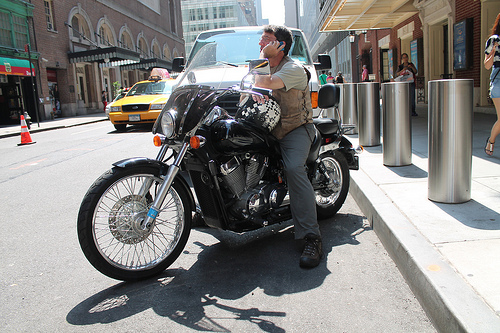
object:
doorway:
[72, 60, 100, 110]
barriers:
[425, 75, 477, 205]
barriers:
[378, 79, 417, 167]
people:
[334, 71, 347, 84]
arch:
[66, 5, 101, 115]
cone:
[16, 112, 38, 147]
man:
[249, 23, 326, 270]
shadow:
[65, 210, 372, 333]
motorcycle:
[76, 42, 359, 281]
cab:
[107, 66, 177, 134]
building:
[27, 0, 185, 121]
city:
[0, 0, 500, 333]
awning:
[67, 46, 143, 69]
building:
[0, 0, 42, 125]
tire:
[76, 164, 194, 284]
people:
[326, 71, 336, 85]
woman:
[482, 10, 500, 157]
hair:
[486, 10, 500, 41]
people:
[396, 52, 420, 116]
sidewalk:
[305, 102, 500, 333]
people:
[361, 65, 369, 82]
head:
[257, 24, 294, 59]